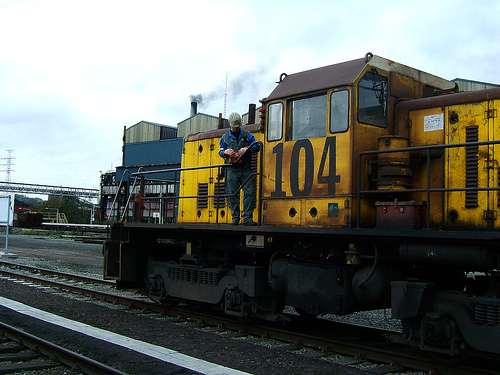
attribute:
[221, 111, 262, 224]
man — conductor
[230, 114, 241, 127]
hat — grey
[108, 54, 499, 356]
train — yellow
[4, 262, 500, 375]
tracks — black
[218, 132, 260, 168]
shirt — blue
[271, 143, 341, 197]
numbers — blue, black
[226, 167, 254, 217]
pants — blue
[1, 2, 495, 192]
sky — blue, white, cloudy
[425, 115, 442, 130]
notice — white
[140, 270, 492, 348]
wheels — black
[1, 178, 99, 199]
bridge — black